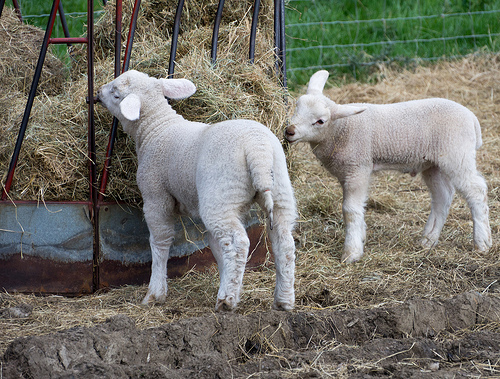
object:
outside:
[26, 16, 488, 360]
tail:
[476, 122, 486, 150]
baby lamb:
[97, 69, 298, 313]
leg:
[264, 204, 297, 304]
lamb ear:
[155, 78, 196, 102]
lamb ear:
[119, 91, 144, 121]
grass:
[358, 12, 441, 47]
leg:
[340, 167, 367, 248]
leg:
[142, 196, 169, 293]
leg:
[202, 213, 248, 298]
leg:
[441, 166, 491, 238]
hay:
[5, 1, 294, 205]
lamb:
[285, 70, 493, 264]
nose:
[284, 123, 297, 138]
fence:
[0, 7, 496, 72]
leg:
[422, 168, 447, 253]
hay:
[0, 48, 500, 378]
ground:
[0, 0, 499, 377]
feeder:
[0, 2, 292, 295]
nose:
[97, 85, 109, 102]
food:
[0, 0, 293, 225]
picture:
[0, 0, 499, 379]